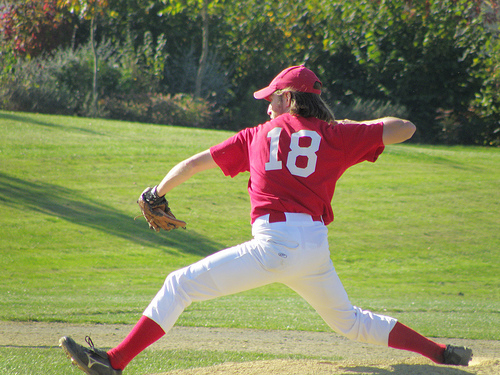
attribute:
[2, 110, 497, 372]
ground — green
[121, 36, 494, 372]
player — baseball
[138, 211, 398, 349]
pants — white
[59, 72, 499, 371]
player — baseball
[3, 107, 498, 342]
lawn — mowed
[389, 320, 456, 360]
socks — red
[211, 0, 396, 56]
leaves — green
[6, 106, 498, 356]
grass — green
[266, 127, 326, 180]
number — 18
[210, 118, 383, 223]
jersey — red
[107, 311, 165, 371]
sock — red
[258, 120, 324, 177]
number — white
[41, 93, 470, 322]
area — grassy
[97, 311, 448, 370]
socks — red